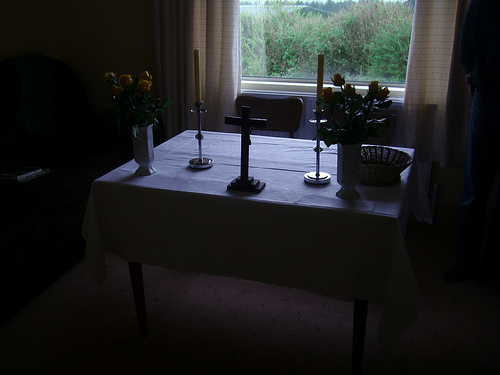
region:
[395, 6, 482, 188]
white curtains on window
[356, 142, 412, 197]
wicker basket on the table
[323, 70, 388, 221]
flowers in a white vase on table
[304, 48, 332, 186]
yellow candle on table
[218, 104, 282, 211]
standing crucifix on table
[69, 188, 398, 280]
white tablecloth on table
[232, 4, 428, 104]
window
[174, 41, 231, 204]
yellow candle in silver holder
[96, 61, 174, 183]
yellow roses in a white vase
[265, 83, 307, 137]
back of chair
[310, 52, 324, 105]
a tall yellow candle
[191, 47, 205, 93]
a tall yellow candle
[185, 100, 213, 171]
a silver candlestick holder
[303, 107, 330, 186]
a silver candlestick holder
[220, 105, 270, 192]
a Christian cross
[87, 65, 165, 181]
a vase of flowers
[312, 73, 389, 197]
a vase of flowers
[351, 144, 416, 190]
a small wicker basket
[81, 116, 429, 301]
a white table cloth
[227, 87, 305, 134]
a back of wood chair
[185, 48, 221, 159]
candle and holder on table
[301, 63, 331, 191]
candle and holder on table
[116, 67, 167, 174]
vase of yellow roses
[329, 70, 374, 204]
vase of yellow roses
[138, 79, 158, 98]
bloom of rose bud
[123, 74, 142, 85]
bloom of rose bud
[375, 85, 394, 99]
bloom of rose bud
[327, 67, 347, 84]
bloom of rose bud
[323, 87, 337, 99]
bloom of rose bud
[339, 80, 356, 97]
bloom of rose bud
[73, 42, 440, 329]
the table has a white tablecloth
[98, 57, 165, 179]
a vase of flowers on the table's corner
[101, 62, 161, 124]
the flowers on the table are roses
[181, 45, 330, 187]
candlesticks are on the table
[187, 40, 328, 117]
the candles are ready to be lit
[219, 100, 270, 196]
a cross is in the middle of the table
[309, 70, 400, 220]
an arrangement of roses are on the table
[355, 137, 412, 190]
an empty basket is near the roses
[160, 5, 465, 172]
the curtains are open in the window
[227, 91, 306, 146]
a chair is behind the table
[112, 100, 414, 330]
white tablecloth on table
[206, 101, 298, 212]
brown cross sitting on table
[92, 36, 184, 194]
flowers sitting on table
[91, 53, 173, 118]
the flowers are yellow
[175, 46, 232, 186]
candles sittings on table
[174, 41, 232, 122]
the candle is yellow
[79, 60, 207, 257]
flowers are sitting in vase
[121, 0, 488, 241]
window with curtain open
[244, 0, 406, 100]
trees outside the window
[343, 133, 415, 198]
basket sitting on table